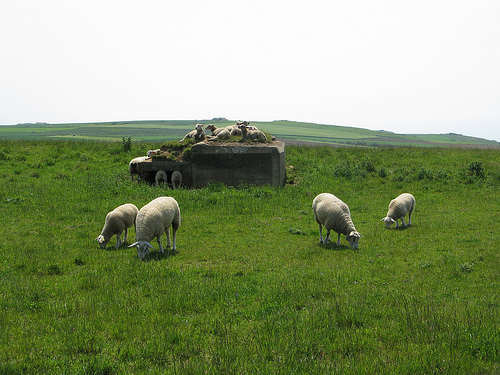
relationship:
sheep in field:
[308, 194, 368, 257] [5, 130, 493, 369]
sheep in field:
[378, 194, 413, 231] [5, 130, 493, 369]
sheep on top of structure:
[182, 116, 263, 145] [133, 138, 289, 193]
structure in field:
[133, 138, 289, 193] [5, 130, 493, 369]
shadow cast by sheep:
[318, 239, 347, 256] [308, 194, 368, 257]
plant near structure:
[119, 134, 134, 156] [133, 138, 289, 193]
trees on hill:
[17, 120, 55, 127] [7, 121, 475, 143]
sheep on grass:
[308, 194, 368, 257] [12, 179, 499, 353]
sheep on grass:
[378, 194, 413, 231] [12, 179, 499, 353]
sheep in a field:
[308, 194, 368, 257] [5, 130, 493, 369]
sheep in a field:
[378, 194, 413, 231] [5, 130, 493, 369]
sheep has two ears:
[308, 194, 368, 257] [350, 230, 362, 242]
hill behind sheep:
[7, 121, 475, 143] [182, 116, 263, 145]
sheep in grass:
[308, 194, 368, 257] [12, 179, 499, 353]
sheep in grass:
[378, 194, 413, 231] [12, 179, 499, 353]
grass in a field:
[12, 179, 499, 353] [5, 130, 493, 369]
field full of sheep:
[5, 130, 493, 369] [308, 194, 368, 257]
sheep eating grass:
[308, 194, 368, 257] [12, 179, 499, 353]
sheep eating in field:
[308, 194, 368, 257] [5, 130, 493, 369]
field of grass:
[5, 130, 493, 369] [12, 179, 499, 353]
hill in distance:
[7, 121, 475, 143] [90, 112, 139, 120]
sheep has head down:
[308, 194, 368, 257] [349, 249, 353, 251]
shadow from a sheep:
[318, 239, 347, 256] [308, 194, 368, 257]